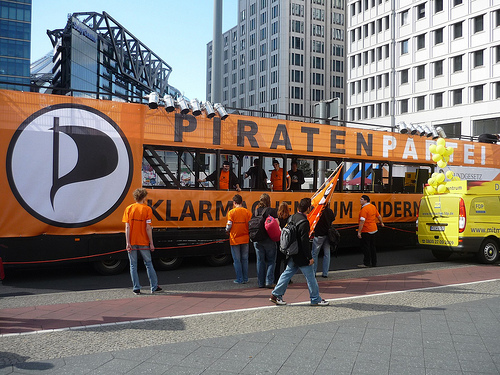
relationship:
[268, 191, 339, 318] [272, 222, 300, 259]
guy carrying backpack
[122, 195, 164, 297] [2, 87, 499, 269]
man standing by bus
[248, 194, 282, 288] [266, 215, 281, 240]
person holding bag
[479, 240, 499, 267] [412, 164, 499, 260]
tire on car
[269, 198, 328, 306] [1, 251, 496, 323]
guy walking down street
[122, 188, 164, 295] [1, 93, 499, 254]
man looking at bus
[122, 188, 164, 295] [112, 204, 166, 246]
man with orange t-shirt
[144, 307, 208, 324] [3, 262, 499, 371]
line on walkway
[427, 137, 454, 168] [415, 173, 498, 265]
balloons on van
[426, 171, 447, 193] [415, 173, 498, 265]
balloons on van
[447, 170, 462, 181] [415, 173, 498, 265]
balloons on van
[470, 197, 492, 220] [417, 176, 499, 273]
blue letters on van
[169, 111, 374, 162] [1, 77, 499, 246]
letters on sign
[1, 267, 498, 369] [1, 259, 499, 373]
shadow on ground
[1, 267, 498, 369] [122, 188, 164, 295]
shadow of man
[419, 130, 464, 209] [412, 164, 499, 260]
balloons on car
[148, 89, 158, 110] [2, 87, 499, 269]
light on bus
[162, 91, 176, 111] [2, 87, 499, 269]
light on bus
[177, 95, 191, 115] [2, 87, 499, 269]
light on bus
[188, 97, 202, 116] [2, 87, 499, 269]
light on bus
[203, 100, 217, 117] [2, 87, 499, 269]
light on bus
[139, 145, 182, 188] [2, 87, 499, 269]
staircase in bus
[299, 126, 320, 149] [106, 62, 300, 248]
letter t on trailer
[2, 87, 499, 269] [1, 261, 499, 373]
bus on road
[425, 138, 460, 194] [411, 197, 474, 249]
balloons attached to vehicle